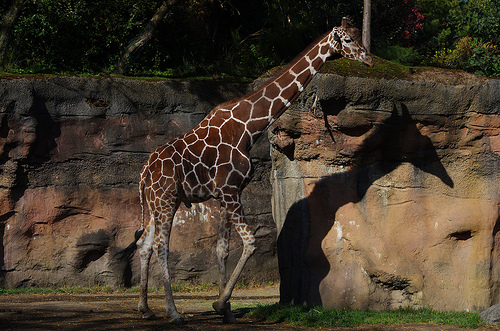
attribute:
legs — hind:
[132, 212, 194, 329]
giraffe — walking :
[101, 12, 403, 321]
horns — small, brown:
[338, 10, 349, 25]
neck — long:
[248, 51, 339, 127]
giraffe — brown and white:
[87, 12, 427, 317]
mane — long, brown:
[246, 29, 335, 105]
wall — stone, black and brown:
[26, 89, 144, 259]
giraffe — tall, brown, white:
[117, 12, 378, 329]